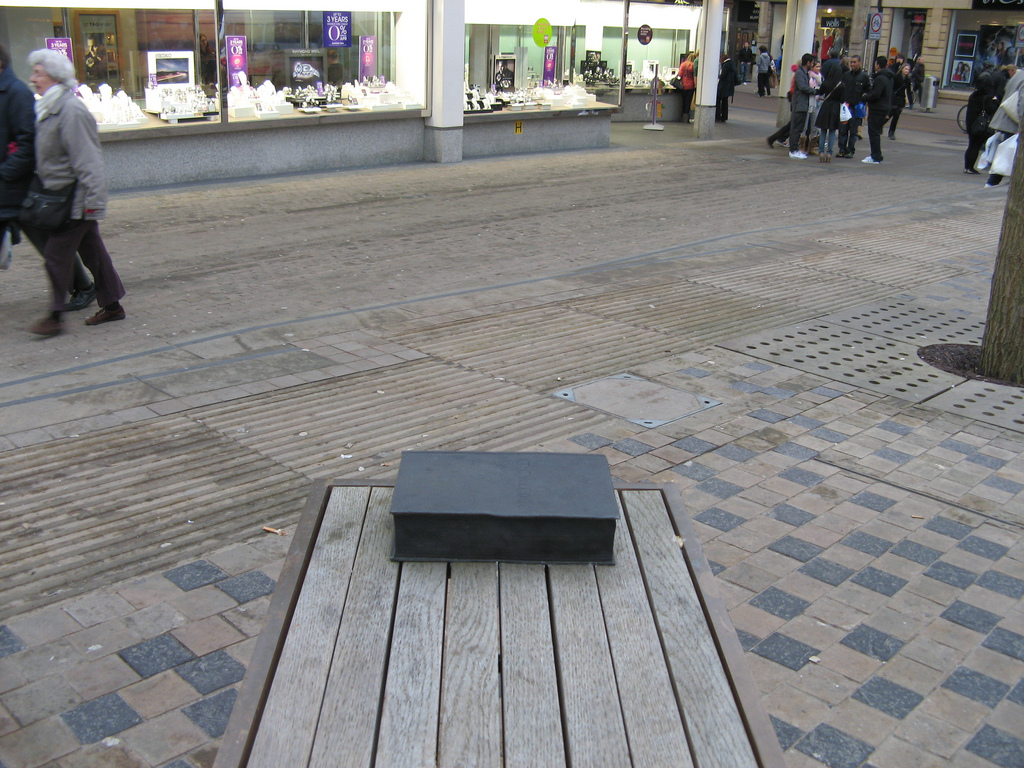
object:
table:
[201, 472, 784, 768]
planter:
[912, 337, 1021, 388]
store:
[0, 0, 729, 193]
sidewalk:
[0, 82, 1024, 767]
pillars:
[688, 0, 725, 142]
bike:
[950, 91, 977, 139]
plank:
[234, 483, 767, 767]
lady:
[14, 39, 134, 336]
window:
[43, 8, 434, 132]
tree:
[959, 91, 1020, 388]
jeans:
[866, 105, 889, 163]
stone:
[111, 631, 203, 683]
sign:
[531, 17, 555, 50]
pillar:
[422, 0, 469, 166]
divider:
[214, 2, 231, 126]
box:
[387, 443, 622, 567]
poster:
[323, 11, 354, 49]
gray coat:
[27, 92, 111, 227]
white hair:
[24, 46, 82, 91]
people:
[762, 51, 917, 168]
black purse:
[19, 173, 78, 239]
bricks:
[782, 413, 824, 431]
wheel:
[950, 96, 977, 140]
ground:
[0, 84, 1024, 763]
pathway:
[102, 211, 748, 361]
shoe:
[860, 157, 880, 166]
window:
[462, 0, 627, 118]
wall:
[0, 0, 1024, 198]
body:
[26, 90, 127, 339]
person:
[837, 53, 871, 160]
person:
[860, 56, 897, 166]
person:
[814, 62, 852, 165]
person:
[786, 52, 821, 161]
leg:
[27, 208, 100, 339]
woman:
[20, 44, 126, 341]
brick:
[783, 482, 856, 517]